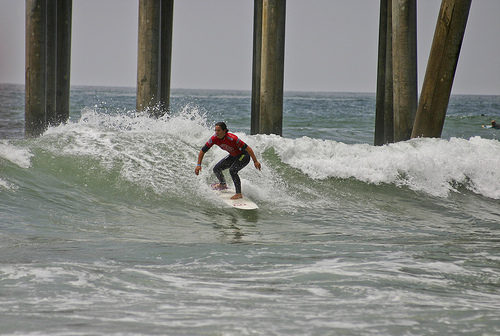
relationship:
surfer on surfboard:
[196, 121, 261, 200] [205, 187, 264, 216]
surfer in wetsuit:
[196, 121, 261, 200] [199, 129, 263, 194]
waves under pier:
[34, 108, 498, 195] [19, 2, 477, 148]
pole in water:
[17, 0, 49, 144] [2, 80, 498, 335]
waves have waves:
[34, 108, 498, 195] [0, 100, 500, 214]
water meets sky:
[2, 80, 498, 335] [4, 3, 498, 96]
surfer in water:
[482, 117, 499, 134] [2, 80, 498, 335]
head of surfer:
[490, 120, 497, 129] [482, 117, 499, 134]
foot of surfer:
[226, 192, 245, 200] [196, 121, 261, 200]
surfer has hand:
[196, 121, 261, 200] [250, 156, 265, 172]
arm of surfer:
[191, 132, 217, 177] [196, 121, 261, 200]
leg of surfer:
[228, 152, 252, 202] [196, 121, 261, 200]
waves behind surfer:
[34, 108, 498, 195] [196, 121, 261, 200]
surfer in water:
[196, 121, 261, 200] [2, 80, 498, 335]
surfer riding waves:
[196, 121, 261, 200] [34, 108, 498, 195]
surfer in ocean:
[196, 121, 261, 200] [2, 80, 498, 335]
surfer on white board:
[196, 121, 261, 200] [205, 187, 264, 216]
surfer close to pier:
[196, 121, 261, 200] [19, 2, 477, 148]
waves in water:
[34, 108, 498, 195] [2, 80, 498, 335]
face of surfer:
[212, 123, 228, 139] [196, 121, 261, 200]